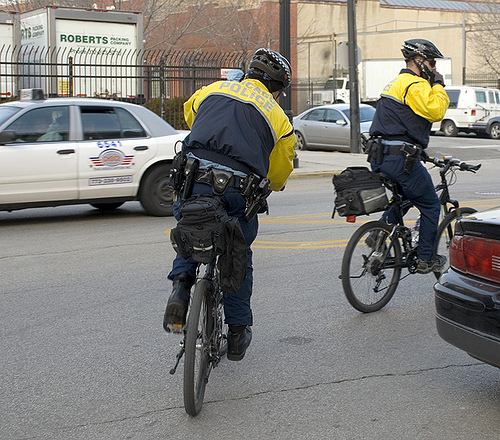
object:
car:
[291, 102, 391, 154]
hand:
[431, 71, 445, 85]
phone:
[414, 60, 436, 82]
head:
[400, 37, 443, 81]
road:
[287, 322, 381, 416]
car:
[0, 88, 193, 217]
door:
[54, 19, 163, 106]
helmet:
[400, 37, 445, 64]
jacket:
[369, 69, 450, 149]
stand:
[170, 345, 185, 375]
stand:
[339, 269, 369, 279]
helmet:
[241, 46, 292, 92]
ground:
[492, 166, 500, 197]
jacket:
[172, 77, 300, 203]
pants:
[367, 140, 440, 262]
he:
[166, 45, 292, 362]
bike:
[169, 148, 298, 415]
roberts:
[60, 34, 108, 44]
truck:
[16, 8, 144, 97]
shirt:
[139, 164, 183, 216]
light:
[446, 232, 500, 284]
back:
[431, 209, 499, 368]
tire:
[340, 220, 403, 313]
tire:
[183, 279, 212, 417]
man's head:
[245, 45, 294, 97]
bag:
[171, 196, 249, 295]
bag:
[329, 162, 388, 213]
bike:
[339, 152, 481, 312]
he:
[361, 38, 453, 275]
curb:
[289, 170, 341, 179]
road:
[11, 232, 165, 409]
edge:
[285, 177, 356, 188]